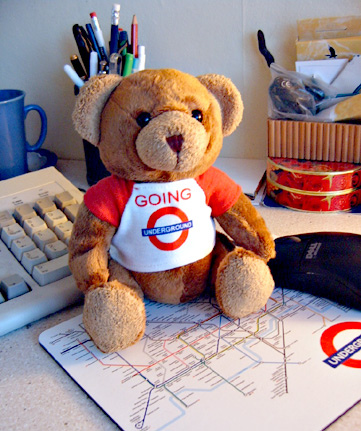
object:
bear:
[69, 68, 277, 355]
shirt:
[82, 165, 244, 273]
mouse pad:
[37, 283, 359, 430]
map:
[49, 283, 360, 431]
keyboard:
[1, 166, 104, 339]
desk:
[4, 158, 359, 430]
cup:
[72, 84, 110, 186]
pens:
[72, 22, 95, 78]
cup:
[1, 88, 48, 179]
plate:
[27, 149, 59, 171]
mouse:
[270, 231, 360, 310]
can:
[265, 157, 361, 214]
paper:
[294, 58, 359, 108]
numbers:
[19, 246, 51, 275]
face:
[98, 67, 225, 182]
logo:
[320, 320, 360, 370]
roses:
[349, 171, 360, 189]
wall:
[1, 2, 360, 157]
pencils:
[129, 11, 138, 58]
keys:
[0, 188, 83, 303]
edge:
[33, 313, 112, 338]